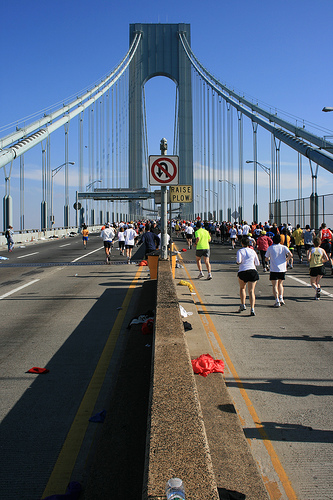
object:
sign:
[148, 154, 179, 186]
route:
[0, 232, 159, 496]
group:
[183, 208, 305, 308]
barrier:
[147, 270, 213, 468]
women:
[234, 236, 261, 316]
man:
[264, 231, 293, 306]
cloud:
[0, 154, 322, 188]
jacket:
[256, 237, 272, 252]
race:
[49, 212, 333, 318]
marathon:
[69, 162, 333, 318]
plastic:
[190, 353, 225, 377]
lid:
[148, 252, 157, 257]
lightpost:
[160, 137, 167, 259]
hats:
[128, 223, 134, 227]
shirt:
[194, 227, 210, 250]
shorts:
[195, 249, 210, 258]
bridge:
[0, 21, 331, 498]